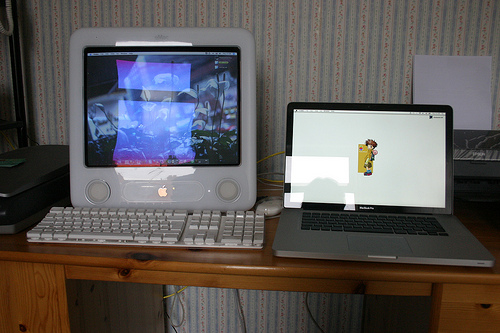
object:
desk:
[1, 178, 499, 332]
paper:
[413, 54, 495, 132]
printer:
[421, 138, 499, 207]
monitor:
[70, 27, 258, 211]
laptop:
[272, 102, 493, 269]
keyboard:
[27, 203, 267, 250]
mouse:
[257, 194, 288, 219]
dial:
[217, 178, 239, 203]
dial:
[86, 181, 109, 204]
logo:
[156, 184, 169, 195]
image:
[355, 139, 380, 173]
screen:
[290, 109, 448, 208]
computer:
[27, 25, 264, 252]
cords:
[167, 287, 187, 325]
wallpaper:
[13, 2, 500, 183]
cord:
[262, 182, 285, 194]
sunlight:
[113, 61, 197, 180]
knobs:
[85, 176, 115, 203]